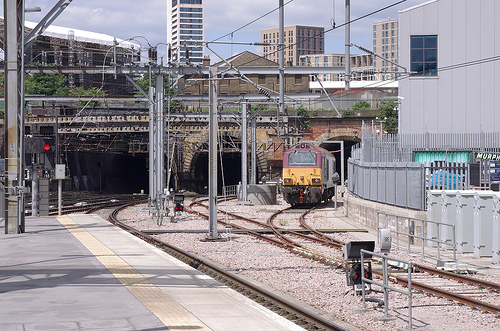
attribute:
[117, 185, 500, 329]
tracks — brown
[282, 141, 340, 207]
engine — red, yellow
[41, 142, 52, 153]
light — red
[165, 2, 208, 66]
building — white, large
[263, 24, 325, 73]
building — brown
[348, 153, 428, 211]
fence — grey, metal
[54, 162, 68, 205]
cannister — tall, grey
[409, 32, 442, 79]
window — dark, paneled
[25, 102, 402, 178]
tunnels — arched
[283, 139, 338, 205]
train — small, red, yellow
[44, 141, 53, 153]
light — red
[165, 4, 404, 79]
buildings — behind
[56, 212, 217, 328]
line — yellow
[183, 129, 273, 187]
archway — round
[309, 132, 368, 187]
archway — on right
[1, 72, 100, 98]
trees — green